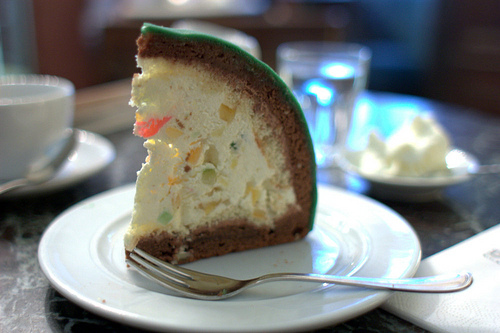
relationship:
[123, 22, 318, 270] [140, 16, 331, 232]
cake topped with icing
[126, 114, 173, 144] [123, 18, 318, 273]
fruit in cake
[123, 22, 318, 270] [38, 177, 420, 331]
cake on plate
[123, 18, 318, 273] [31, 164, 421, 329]
cake on round plate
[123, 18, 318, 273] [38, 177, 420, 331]
cake on plate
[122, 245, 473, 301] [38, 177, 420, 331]
fork on plate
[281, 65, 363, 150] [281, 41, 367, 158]
water in glass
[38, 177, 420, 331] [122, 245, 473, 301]
plate with fork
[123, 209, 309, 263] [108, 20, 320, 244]
layer belonging to cake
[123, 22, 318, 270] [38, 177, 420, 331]
cake sitting on top of plate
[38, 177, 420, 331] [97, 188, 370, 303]
plate has edge